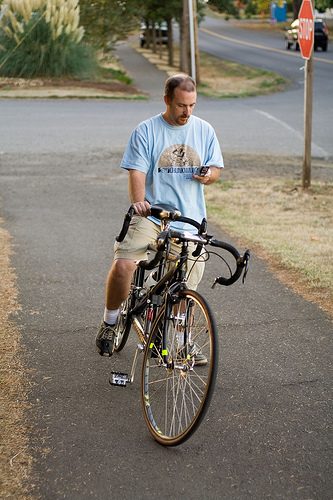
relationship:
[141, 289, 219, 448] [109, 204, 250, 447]
wheel on bicycle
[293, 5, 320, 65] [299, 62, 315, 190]
sign on wooden post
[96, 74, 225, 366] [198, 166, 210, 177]
guy looking at cellphone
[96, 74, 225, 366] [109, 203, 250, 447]
guy leaning on bicycle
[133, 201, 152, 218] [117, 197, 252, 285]
hand on handle bar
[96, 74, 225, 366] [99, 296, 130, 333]
guy wearing socks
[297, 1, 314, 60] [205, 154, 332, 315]
sign on brown grass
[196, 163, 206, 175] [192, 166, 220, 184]
cellphone in hand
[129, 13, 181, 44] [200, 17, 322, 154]
truck parked on road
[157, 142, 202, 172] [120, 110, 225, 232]
logo on blue shirt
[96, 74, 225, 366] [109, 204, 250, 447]
guy on a bicycle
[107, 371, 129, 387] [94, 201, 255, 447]
pedal on a bicycle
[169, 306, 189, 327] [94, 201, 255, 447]
pedal on a bicycle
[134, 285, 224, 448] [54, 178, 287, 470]
wheel on a bicycle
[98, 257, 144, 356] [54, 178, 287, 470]
wheel on a bicycle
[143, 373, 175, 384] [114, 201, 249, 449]
spoke on a bike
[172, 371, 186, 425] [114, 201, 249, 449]
spoke on a bike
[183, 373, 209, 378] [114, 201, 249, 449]
spoke on a bike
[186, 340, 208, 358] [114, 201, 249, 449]
spoke on a bike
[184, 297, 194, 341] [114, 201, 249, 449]
spoke on a bike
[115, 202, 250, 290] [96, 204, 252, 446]
handle bar on bike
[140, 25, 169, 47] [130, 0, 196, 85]
van parked behind trees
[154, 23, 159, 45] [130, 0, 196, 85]
van parked behind trees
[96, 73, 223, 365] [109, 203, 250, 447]
guy on bicycle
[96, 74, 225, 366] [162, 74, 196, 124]
guy has head